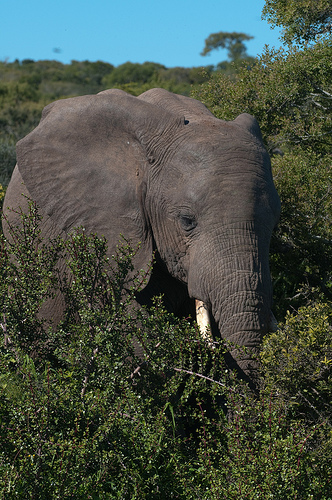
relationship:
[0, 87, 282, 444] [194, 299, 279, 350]
elephant has tusks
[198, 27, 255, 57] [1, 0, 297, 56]
tree against sky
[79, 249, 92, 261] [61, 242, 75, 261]
leaves on stems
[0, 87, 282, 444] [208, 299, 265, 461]
elephant has trunk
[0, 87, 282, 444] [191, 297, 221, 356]
elephant has tusk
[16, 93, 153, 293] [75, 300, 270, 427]
ear in bushes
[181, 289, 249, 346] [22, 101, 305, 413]
tusk on elephant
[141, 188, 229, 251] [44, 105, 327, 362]
eye on elephant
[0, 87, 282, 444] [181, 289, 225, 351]
elephant has tusk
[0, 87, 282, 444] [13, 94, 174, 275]
elephant has ear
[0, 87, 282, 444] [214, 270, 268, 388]
elephant has trunk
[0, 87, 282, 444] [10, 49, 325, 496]
elephant in bushes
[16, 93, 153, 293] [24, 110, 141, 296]
ear right ear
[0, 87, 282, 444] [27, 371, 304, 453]
elephant in forest brush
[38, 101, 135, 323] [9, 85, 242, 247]
large ear on elephant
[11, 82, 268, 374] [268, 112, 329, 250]
elephant in tree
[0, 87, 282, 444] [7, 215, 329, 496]
elephant in bushes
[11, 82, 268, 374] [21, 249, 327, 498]
elephant in bushes